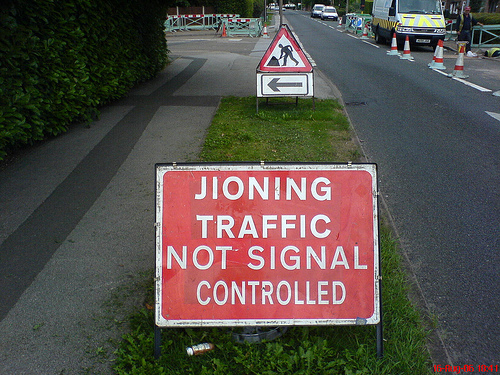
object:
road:
[374, 0, 498, 375]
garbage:
[185, 340, 217, 357]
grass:
[106, 95, 439, 373]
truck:
[366, 0, 448, 47]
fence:
[161, 13, 261, 36]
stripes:
[225, 17, 254, 23]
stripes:
[164, 12, 238, 19]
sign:
[257, 23, 314, 73]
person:
[459, 4, 476, 56]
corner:
[243, 17, 345, 78]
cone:
[359, 22, 371, 40]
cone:
[387, 32, 400, 56]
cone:
[401, 35, 415, 60]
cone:
[430, 41, 448, 70]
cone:
[451, 42, 469, 78]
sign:
[155, 161, 374, 329]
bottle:
[185, 340, 217, 358]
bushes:
[0, 7, 173, 138]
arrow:
[266, 76, 304, 92]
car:
[312, 3, 327, 18]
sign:
[253, 71, 313, 99]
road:
[0, 6, 164, 374]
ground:
[0, 84, 500, 371]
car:
[319, 4, 338, 22]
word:
[194, 174, 330, 200]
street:
[0, 10, 498, 373]